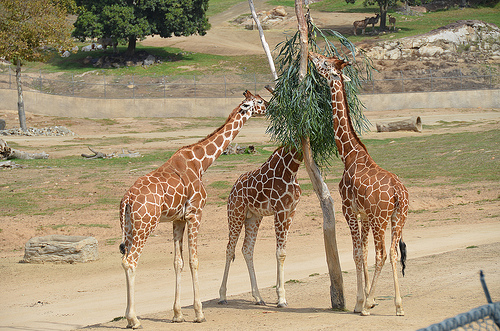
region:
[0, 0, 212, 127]
Trees are in the background.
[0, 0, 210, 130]
The trees have leaves.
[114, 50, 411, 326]
The giraffes are eating.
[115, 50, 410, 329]
Three giraffes are eating.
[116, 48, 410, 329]
The giraffes are tall.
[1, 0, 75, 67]
The leaves are yellow.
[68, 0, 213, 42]
The leaves are green.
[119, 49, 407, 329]
The giraffes are brown and white.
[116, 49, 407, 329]
The giraffes have brown spots.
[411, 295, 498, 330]
A fence is in the lower right.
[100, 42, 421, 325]
Three giraffes eating green leaves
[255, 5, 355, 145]
Green tree limb hanging down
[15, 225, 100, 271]
A square rock on ground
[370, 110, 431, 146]
An oblong pipe on the ground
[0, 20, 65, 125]
A small green tree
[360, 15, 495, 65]
A rocky hill on other side of fence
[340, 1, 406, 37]
Animals under a tree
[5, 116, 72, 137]
Small rocks around a tree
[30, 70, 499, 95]
A long metal fence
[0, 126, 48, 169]
Dead log laying on ground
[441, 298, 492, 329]
silver metal chain link fence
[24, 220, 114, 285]
square shaped stone located on left of photo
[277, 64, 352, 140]
green leafy branch being eaten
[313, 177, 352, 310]
skinny light brown tree trunk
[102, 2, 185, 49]
green leafs on tree in distance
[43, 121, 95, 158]
pile of grey rocks by tree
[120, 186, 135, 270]
tail on back of giraffee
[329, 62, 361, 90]
left ear on giraffee's head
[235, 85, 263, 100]
horns on top of giraffee's head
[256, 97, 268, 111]
dark eye on giraffee's head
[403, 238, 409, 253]
tail of a giraffe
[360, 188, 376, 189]
back of a giraffe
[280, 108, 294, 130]
part of a grass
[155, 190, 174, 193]
part of a giraffe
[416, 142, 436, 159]
part of a grass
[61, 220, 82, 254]
edge of a rock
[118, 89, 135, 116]
part of a fence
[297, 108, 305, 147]
edge of a tree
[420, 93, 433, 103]
part of a fence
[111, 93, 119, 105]
edge of a fence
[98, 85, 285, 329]
tan and brown spotted giraffe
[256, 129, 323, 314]
tan and brown spotted giraffe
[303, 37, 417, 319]
tan and brown spotted giraffe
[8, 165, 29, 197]
short green and brown grass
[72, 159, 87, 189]
short green and brown grass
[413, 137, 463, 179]
short green and brown grass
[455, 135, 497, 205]
short green and brown grass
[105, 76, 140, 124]
short green and brown grass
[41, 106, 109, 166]
short green and brown grass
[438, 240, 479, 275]
short green and brown grass